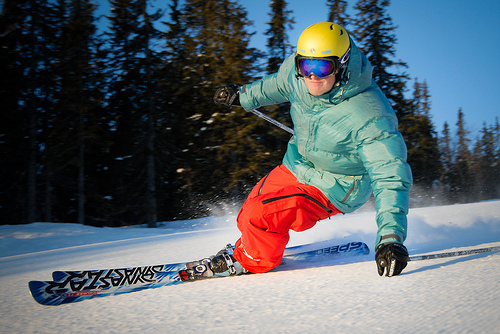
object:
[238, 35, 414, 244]
blue jacket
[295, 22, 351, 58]
helmet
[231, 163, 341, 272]
pants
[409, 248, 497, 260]
pole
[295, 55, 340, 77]
goggles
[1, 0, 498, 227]
trees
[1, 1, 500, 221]
forest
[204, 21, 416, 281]
person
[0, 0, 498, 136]
sky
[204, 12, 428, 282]
skier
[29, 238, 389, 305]
board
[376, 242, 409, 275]
glove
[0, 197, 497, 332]
snow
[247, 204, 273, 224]
track